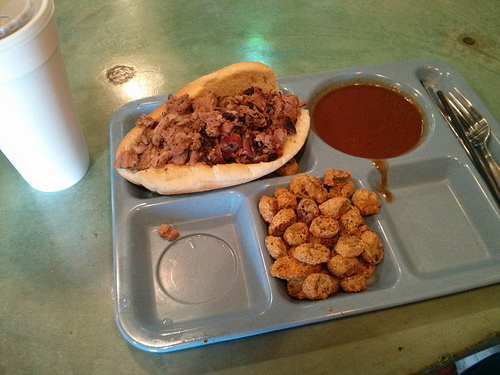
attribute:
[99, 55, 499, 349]
tray — blue, grey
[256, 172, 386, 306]
breadcrumbs — brown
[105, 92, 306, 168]
meat — red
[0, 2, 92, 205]
cup — styrofoam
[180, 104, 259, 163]
chunk — food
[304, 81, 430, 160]
sauce — some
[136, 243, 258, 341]
part of tray — empty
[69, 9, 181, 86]
object — table